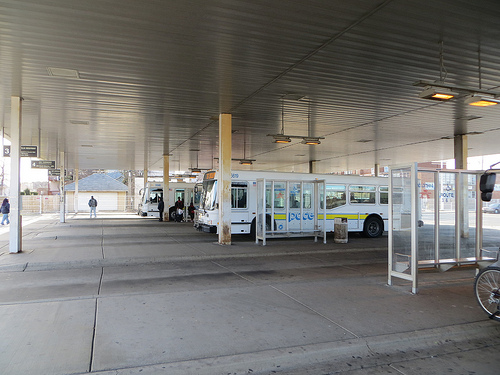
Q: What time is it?
A: Daytime.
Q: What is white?
A: The buses.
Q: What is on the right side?
A: A bike.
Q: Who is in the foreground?
A: No one.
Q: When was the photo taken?
A: During the day.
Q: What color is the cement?
A: Gray.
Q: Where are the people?
A: At the bus terminal.